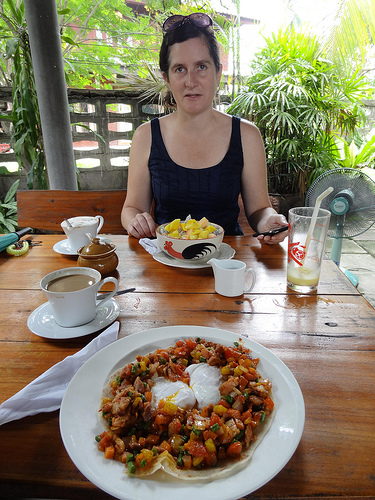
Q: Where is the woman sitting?
A: At a table.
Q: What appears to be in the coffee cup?
A: Coffee.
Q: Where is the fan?
A: On the ground.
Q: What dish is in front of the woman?
A: Bowl.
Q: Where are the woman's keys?
A: Next to the umbrella.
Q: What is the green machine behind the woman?
A: Fan.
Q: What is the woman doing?
A: Sitting on a bench.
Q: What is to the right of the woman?
A: A blue fan.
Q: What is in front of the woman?
A: A bowl of food.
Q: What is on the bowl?
A: A rooster.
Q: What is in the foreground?
A: A plate with food on it.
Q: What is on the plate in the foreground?
A: Eggs with hash of potatoes and meat on a tortilla.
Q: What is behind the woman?
A: A fence.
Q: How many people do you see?
A: 1.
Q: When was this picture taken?
A: During daylight.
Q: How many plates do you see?
A: 4.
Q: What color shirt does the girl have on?
A: Black.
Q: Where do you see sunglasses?
A: On top the girls head.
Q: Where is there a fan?
A: Right side of the picture.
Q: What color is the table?
A: Brown.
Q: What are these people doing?
A: Eating.